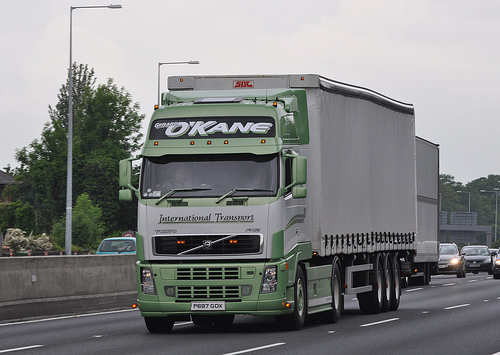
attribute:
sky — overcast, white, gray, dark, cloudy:
[234, 7, 415, 48]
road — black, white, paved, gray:
[422, 284, 481, 353]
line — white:
[361, 310, 400, 334]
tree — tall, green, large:
[52, 75, 131, 180]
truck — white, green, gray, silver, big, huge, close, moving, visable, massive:
[131, 69, 422, 335]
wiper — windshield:
[217, 178, 275, 208]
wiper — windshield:
[153, 175, 210, 212]